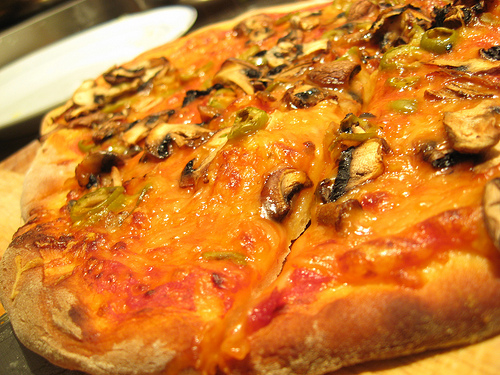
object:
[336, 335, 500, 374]
cuttingboard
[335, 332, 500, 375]
wood board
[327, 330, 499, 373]
table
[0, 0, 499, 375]
crust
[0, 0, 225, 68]
counter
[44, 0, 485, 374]
cheese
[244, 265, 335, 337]
sauce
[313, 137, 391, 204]
mushrooms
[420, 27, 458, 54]
pepper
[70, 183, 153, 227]
pepper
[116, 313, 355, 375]
crust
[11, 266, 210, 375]
crust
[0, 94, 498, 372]
pizza crust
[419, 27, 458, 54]
olive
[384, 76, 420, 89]
olive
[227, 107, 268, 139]
olive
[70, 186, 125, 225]
olive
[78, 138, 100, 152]
olive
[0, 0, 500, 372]
pizza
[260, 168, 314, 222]
mushroom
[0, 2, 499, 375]
layer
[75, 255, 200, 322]
sauce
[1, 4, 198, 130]
plate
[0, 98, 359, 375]
slice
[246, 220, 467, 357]
crust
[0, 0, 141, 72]
backsplash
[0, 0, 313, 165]
background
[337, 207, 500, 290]
tomato sauce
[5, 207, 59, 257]
crust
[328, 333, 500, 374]
surface